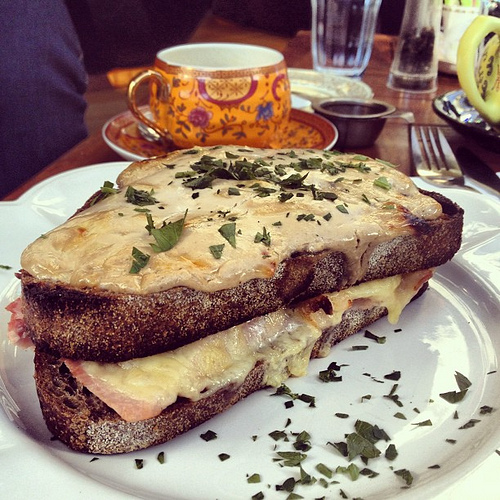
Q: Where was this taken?
A: A restaurant.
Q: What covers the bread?
A: Melted cheese.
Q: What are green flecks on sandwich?
A: Parsley.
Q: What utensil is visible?
A: Fork.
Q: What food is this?
A: Sandwich.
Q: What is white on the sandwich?
A: Cheese.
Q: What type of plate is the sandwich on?
A: White flower shaped.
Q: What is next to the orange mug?
A: Small silver cup.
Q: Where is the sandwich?
A: On the plate.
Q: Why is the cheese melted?
A: It was cooked.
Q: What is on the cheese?
A: Cilantro.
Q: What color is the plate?
A: White.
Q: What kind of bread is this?
A: Rye.